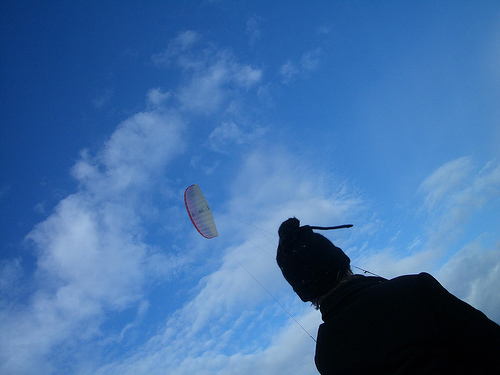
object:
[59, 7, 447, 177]
blue sky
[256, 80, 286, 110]
cloud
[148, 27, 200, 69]
cloud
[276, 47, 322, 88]
cloud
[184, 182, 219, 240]
parasailing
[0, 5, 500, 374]
sky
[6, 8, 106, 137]
sky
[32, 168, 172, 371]
clouds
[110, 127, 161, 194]
cloud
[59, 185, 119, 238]
cloud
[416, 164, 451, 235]
cloud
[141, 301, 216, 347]
cloud